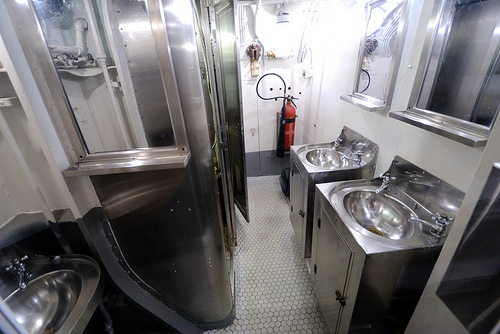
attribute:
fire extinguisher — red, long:
[269, 82, 309, 162]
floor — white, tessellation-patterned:
[232, 173, 316, 333]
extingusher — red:
[258, 71, 296, 151]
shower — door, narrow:
[201, 7, 266, 231]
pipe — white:
[72, 7, 145, 142]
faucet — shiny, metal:
[408, 211, 454, 241]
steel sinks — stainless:
[281, 125, 466, 331]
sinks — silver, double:
[272, 121, 442, 263]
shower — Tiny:
[31, 3, 239, 273]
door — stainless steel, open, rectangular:
[186, 5, 253, 227]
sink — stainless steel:
[285, 130, 375, 178]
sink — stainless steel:
[318, 178, 448, 255]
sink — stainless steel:
[0, 252, 99, 332]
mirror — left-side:
[23, 0, 196, 180]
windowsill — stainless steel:
[62, 155, 190, 180]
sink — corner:
[2, 236, 114, 318]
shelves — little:
[338, 87, 493, 160]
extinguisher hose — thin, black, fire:
[255, 67, 297, 147]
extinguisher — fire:
[255, 90, 321, 139]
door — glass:
[216, 0, 252, 230]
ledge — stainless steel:
[393, 106, 480, 152]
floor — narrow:
[242, 223, 307, 328]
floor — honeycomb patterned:
[244, 178, 319, 328]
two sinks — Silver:
[286, 121, 430, 270]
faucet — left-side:
[3, 253, 32, 289]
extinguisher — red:
[255, 73, 297, 153]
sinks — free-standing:
[289, 125, 379, 181]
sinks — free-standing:
[316, 153, 460, 252]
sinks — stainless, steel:
[280, 124, 475, 331]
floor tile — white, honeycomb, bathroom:
[203, 173, 325, 332]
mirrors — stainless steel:
[348, 3, 498, 129]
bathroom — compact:
[0, 0, 499, 330]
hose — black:
[250, 70, 295, 105]